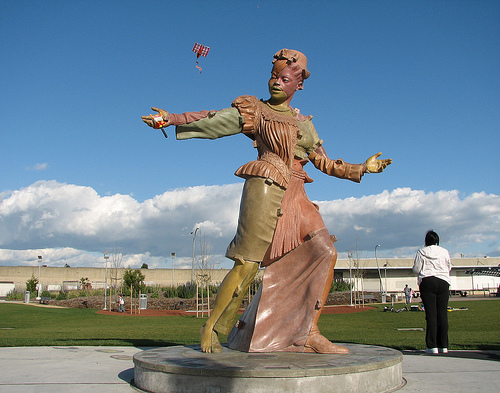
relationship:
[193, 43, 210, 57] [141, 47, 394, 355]
kite above statue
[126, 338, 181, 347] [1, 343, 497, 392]
shadow on top of ground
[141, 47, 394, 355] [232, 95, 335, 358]
women wearing dress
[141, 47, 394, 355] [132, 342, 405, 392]
statue standing on concrete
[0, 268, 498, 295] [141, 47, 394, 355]
building behind statue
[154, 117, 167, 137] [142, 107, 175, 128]
object in hand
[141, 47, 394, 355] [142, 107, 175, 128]
statue looking at hand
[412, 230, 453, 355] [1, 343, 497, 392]
person standing on concrete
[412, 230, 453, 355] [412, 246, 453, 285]
person wearing hoodie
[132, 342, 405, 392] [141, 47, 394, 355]
cement base under statue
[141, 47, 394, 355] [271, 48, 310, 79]
statue wearing bonnet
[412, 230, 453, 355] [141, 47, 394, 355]
person right of statue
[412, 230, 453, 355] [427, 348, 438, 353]
person wearing shoe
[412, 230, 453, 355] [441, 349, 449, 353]
person wearing shoe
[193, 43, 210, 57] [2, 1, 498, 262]
kite in sky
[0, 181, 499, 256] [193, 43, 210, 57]
cloud beneath kite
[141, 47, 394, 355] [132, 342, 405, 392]
statue on concrete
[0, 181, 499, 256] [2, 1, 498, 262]
clouds in sky